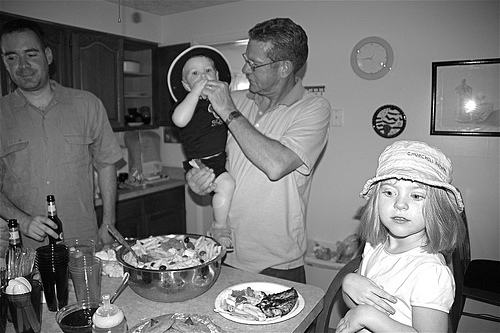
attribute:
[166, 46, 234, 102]
hat — black, white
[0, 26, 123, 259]
man — drinking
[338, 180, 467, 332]
girl — blond, young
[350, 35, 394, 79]
clock — round, plastic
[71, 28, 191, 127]
cabinet — open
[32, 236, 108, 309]
cups — plastic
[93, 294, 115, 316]
nipple — plastic, clear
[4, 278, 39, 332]
spoons — plastic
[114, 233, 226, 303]
bowl — steel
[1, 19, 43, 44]
hair — dark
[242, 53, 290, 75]
glasses — wire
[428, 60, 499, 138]
picture frame — rectangular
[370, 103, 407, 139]
picture — round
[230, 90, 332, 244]
shirt — short sleeve